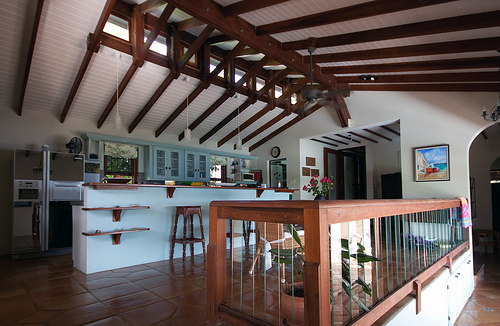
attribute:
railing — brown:
[231, 226, 293, 284]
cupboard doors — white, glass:
[147, 141, 212, 184]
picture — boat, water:
[409, 143, 451, 182]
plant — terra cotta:
[264, 223, 383, 294]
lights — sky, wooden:
[92, 3, 304, 115]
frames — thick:
[3, 3, 488, 150]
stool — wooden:
[164, 202, 209, 264]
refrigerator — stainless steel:
[1, 146, 87, 264]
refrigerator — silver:
[9, 140, 81, 258]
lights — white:
[105, 60, 253, 149]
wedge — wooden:
[163, 187, 177, 199]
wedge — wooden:
[254, 190, 262, 196]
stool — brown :
[167, 197, 206, 262]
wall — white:
[0, 0, 499, 263]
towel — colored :
[444, 193, 481, 231]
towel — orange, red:
[449, 196, 473, 231]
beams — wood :
[57, 3, 497, 142]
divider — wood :
[303, 169, 472, 319]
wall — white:
[242, 91, 498, 198]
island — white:
[64, 179, 298, 276]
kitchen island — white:
[74, 173, 305, 275]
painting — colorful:
[411, 141, 451, 184]